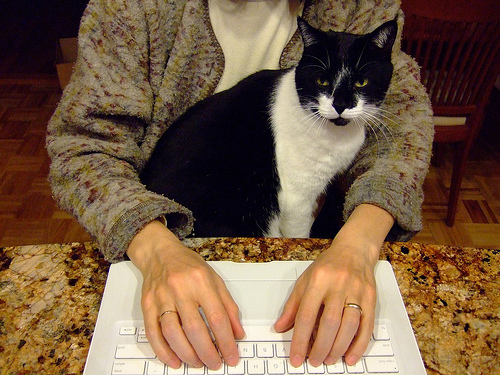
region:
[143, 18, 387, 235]
black and white seated cat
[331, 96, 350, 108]
Nose of black and white cat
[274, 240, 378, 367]
Hand of person holding cat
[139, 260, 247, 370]
Hand of person holding cat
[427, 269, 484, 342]
Multicolored table in seating area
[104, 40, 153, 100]
Part of multicolored jacket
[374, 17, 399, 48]
Ear of black and white cat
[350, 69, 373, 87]
Eye of black and white cat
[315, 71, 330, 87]
Eye of black and white cat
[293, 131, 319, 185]
Part of white chest of cat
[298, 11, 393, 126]
Head of black and white cat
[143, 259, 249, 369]
Hand of person holding cat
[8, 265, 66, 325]
Multicolored table in seating area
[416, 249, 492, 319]
Multicolored table in seating area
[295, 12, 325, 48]
Ear of black and white cat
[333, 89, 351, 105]
Note of black and white cat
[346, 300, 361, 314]
A ring on the left ring finger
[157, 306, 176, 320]
A ring on the right ring finger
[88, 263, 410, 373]
A white keyboard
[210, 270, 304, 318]
A touchpad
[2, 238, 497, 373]
A brown and tan granite table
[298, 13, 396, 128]
The face of a black and white cat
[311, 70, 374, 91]
The yellow eyes of a cat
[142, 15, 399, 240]
A cat sitting in a person's lap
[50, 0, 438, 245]
A person wearing a gray sweater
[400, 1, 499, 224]
The back of a dark wooden chair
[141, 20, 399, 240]
black and white cat sitting in woman's lap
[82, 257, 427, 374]
white laptop keyboard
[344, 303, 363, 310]
silver wedding ring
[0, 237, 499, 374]
marble table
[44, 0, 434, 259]
grey housecoat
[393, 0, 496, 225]
wooden chair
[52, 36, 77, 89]
brown cardboard box on floor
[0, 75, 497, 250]
parquet tiles on floor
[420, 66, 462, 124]
white seat cushion on wood chair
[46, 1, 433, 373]
woman typing on white laptop keyboard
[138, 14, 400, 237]
The cat is black and white.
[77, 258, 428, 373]
The keyboard is white.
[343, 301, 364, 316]
The woman wears a ring.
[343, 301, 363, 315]
The ring is gold colored.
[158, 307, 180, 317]
The woman is wearing a ring.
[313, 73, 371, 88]
The cat has yellow eyes.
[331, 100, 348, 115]
The cat has a black nose.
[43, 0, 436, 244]
The sweater is gray.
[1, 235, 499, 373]
The table is speckled granite.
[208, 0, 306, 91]
The woman wears a white shirt.